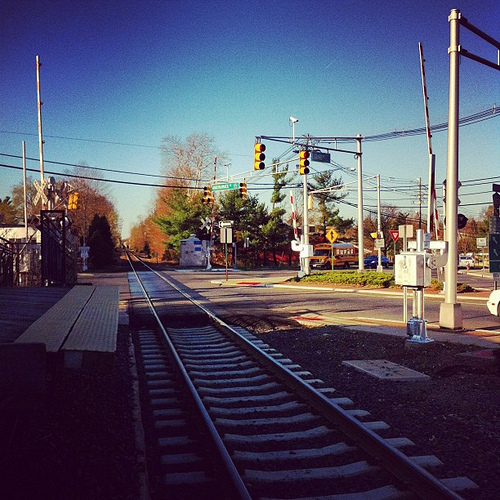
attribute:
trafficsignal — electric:
[253, 135, 267, 170]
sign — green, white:
[207, 180, 244, 192]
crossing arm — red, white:
[418, 40, 446, 247]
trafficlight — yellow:
[251, 137, 271, 172]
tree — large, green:
[256, 170, 300, 264]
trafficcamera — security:
[287, 115, 298, 138]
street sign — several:
[491, 235, 498, 272]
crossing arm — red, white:
[282, 185, 311, 258]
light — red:
[229, 124, 395, 191]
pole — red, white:
[32, 51, 48, 183]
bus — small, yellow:
[311, 239, 357, 267]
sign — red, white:
[200, 162, 242, 201]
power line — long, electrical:
[3, 146, 490, 232]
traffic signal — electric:
[297, 149, 312, 176]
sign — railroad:
[23, 164, 83, 238]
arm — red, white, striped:
[287, 190, 300, 243]